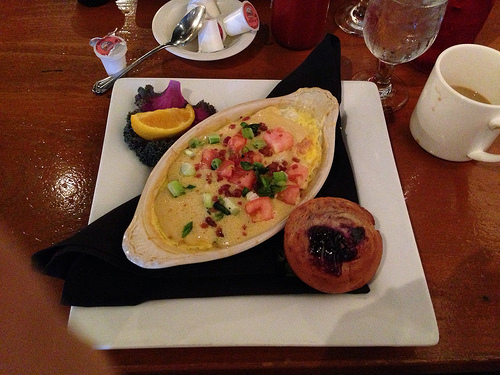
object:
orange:
[126, 103, 198, 143]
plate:
[55, 72, 443, 355]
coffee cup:
[404, 37, 500, 167]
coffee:
[448, 82, 491, 105]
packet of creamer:
[86, 32, 132, 77]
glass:
[332, 0, 453, 115]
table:
[2, 1, 499, 375]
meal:
[117, 84, 344, 273]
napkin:
[88, 2, 210, 96]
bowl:
[146, 0, 266, 65]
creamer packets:
[219, 0, 263, 38]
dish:
[117, 84, 343, 272]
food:
[148, 104, 328, 256]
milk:
[109, 43, 126, 56]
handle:
[465, 117, 500, 165]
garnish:
[121, 79, 219, 169]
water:
[352, 0, 451, 70]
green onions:
[289, 154, 301, 166]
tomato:
[243, 195, 275, 223]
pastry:
[278, 195, 387, 297]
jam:
[304, 219, 368, 279]